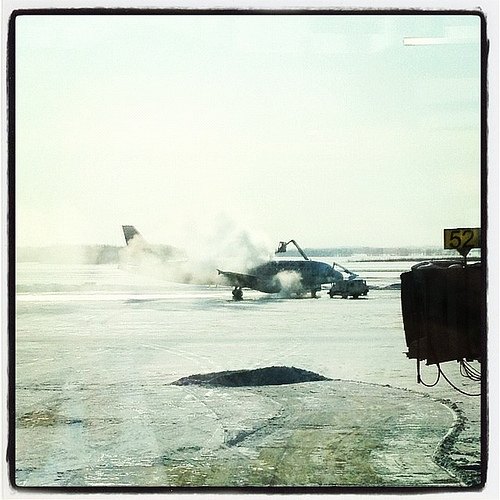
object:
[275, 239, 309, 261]
crane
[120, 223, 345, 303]
airplane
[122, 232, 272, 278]
smoke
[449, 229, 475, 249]
number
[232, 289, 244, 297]
landing gear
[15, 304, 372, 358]
gray pathway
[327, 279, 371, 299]
truck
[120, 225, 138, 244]
blocked tail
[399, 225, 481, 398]
equipment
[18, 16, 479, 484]
day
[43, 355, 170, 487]
skid marks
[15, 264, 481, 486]
pathway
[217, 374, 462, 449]
tire tracks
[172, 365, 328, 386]
dirt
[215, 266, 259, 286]
wing